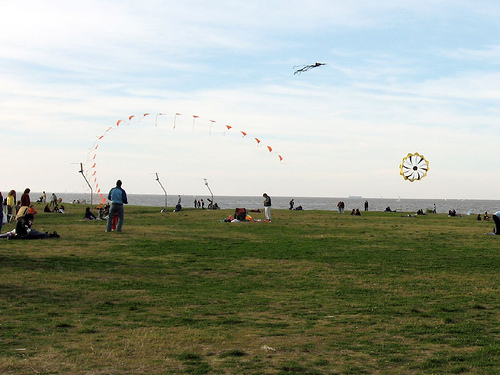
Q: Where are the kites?
A: In the sky.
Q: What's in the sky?
A: Kites.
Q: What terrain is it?
A: Field.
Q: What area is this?
A: Park.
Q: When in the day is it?
A: Afternoon.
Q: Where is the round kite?
A: Right.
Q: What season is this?
A: Spring.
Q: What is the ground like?
A: Patchy.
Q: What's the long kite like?
A: Snake.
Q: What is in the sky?
A: Kites.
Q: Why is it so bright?
A: Sunshine.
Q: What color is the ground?
A: Green.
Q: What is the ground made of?
A: Grass.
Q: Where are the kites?
A: The sky.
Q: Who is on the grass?
A: Men and woman.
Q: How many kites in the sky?
A: Three.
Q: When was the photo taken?
A: Day time.